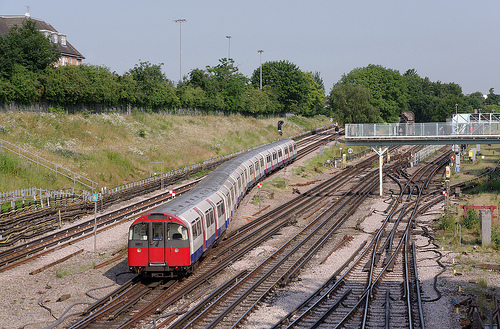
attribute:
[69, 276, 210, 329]
track — train track, empty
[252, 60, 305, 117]
tree — green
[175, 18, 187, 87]
post — behind fence, tall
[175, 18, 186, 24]
light — street light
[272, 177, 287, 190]
grass — green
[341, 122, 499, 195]
platform — small, elevated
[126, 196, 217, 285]
car — red, silver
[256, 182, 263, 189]
flag — small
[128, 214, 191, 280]
front — red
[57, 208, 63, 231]
pole — metal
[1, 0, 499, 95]
sky — blue, hazy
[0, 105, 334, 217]
hill — below trees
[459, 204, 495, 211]
sign — red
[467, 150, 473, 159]
marker — yellow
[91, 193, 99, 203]
sign — blue, small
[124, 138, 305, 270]
train — commuter, long, silver, grey